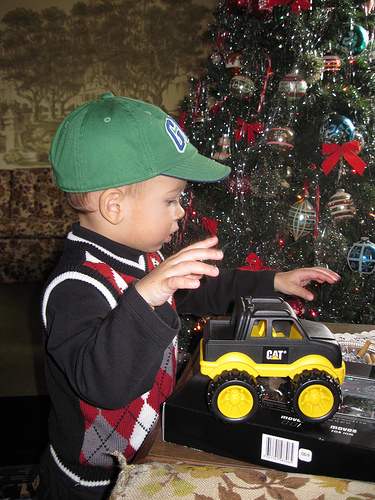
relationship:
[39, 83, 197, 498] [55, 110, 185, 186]
boy wearing cap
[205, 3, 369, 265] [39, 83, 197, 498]
christmas tree next to boy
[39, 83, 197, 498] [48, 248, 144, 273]
boy wearing sweater  vest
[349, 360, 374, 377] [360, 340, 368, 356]
ashtray with cigarette butt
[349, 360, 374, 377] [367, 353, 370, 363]
ashtray with cigarette butt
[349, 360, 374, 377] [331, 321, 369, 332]
ashtray sitting on table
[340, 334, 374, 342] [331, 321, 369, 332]
doily laying on table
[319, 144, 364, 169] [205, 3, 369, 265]
bow tied on christmas tree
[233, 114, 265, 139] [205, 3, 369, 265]
bow tied on christmas tree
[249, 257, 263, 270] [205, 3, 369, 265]
bow tied on christmas tree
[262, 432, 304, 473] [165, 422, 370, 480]
bar code printed on box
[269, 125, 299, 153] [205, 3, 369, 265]
ornament hanging on christmas tree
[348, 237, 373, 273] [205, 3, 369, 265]
ornament hanging on christmas tree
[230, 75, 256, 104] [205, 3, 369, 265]
ornament hanging on christmas tree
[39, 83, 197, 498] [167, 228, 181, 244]
boy has mouth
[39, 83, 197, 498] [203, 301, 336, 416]
boy playing with toy truck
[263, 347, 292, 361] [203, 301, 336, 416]
logo painted on toy truck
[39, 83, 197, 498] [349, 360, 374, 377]
boy reaching for ashtray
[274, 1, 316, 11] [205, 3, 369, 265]
bow tied on christmas tree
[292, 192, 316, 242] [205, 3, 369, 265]
bulb hanging on christmas tree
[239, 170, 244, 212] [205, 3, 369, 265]
tinsel draped onto christmas tree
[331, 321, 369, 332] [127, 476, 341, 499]
table next to sofa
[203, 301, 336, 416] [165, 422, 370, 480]
toy truck sitting on box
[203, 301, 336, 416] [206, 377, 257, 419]
toy truck has tire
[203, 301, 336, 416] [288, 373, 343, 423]
toy truck has tire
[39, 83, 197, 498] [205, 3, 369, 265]
boy standing next to christmas tree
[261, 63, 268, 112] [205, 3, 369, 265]
candy cane hanging onto christmas tree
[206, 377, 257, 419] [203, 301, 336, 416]
tire underneath toy truck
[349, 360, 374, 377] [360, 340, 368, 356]
ashtray holding cigarette butt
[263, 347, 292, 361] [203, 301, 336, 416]
logo printed on toy truck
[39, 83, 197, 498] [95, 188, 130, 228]
boy has ear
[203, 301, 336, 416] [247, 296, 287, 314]
toy truck has roof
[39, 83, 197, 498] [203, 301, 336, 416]
boy opening toy truck